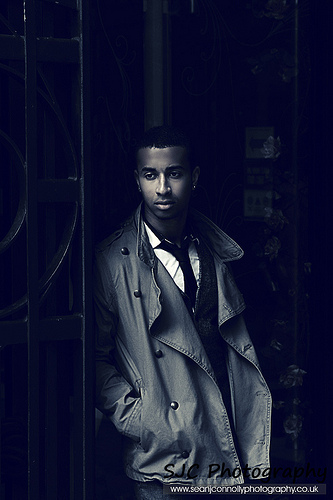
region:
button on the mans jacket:
[166, 399, 181, 414]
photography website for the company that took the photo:
[166, 482, 326, 494]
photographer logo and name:
[162, 462, 328, 483]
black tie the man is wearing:
[156, 237, 216, 311]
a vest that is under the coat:
[190, 238, 222, 365]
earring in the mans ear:
[192, 181, 199, 192]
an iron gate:
[4, 95, 89, 276]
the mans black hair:
[136, 129, 198, 148]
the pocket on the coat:
[123, 394, 153, 456]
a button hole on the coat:
[235, 341, 260, 358]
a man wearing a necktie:
[141, 211, 216, 299]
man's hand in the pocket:
[78, 317, 181, 488]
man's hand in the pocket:
[107, 380, 166, 452]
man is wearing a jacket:
[96, 217, 285, 485]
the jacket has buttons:
[119, 253, 186, 429]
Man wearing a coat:
[86, 200, 279, 489]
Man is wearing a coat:
[84, 195, 275, 484]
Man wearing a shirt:
[137, 216, 207, 303]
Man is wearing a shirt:
[139, 218, 205, 306]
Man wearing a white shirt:
[143, 217, 205, 311]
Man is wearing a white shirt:
[140, 218, 204, 311]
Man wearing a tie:
[157, 236, 205, 304]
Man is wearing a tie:
[150, 233, 205, 311]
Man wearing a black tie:
[155, 232, 208, 306]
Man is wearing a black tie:
[156, 235, 211, 307]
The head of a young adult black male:
[128, 123, 210, 223]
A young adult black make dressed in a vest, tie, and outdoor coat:
[131, 125, 232, 296]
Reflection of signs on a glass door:
[233, 117, 288, 230]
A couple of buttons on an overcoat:
[141, 345, 185, 418]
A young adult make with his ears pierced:
[128, 116, 206, 223]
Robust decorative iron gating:
[2, 8, 94, 440]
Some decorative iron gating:
[3, 2, 98, 498]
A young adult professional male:
[97, 123, 271, 444]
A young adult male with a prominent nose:
[127, 122, 204, 225]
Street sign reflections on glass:
[228, 102, 294, 232]